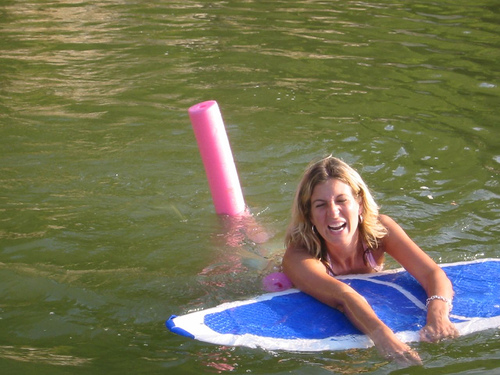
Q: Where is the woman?
A: On a surfboard.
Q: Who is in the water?
A: A woman with blonde hair.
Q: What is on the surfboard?
A: The arm of a woman.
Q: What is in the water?
A: A blue and white surfboard.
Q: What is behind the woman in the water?
A: A pink pole.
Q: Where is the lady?
A: On surfboard.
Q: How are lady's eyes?
A: Closed.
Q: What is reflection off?
A: Water.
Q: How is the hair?
A: Blonde.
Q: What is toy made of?
A: Foam.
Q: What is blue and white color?
A: Surfboard.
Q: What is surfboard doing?
A: Floating.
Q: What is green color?
A: Water.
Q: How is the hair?
A: Shoulder length.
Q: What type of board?
A: Surfboard.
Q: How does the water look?
A: Murky.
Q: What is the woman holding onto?
A: A surfboard.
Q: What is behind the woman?
A: A pink tube.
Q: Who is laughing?
A: Woman in water.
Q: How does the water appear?
A: Calm.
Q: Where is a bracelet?
A: Around woman's wrist.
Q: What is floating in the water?
A: The pink tube.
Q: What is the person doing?
A: Swimming.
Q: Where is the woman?
A: In the water.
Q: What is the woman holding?
A: A kickboard.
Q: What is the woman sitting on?
A: A pool noodle.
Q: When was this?
A: Daytime.